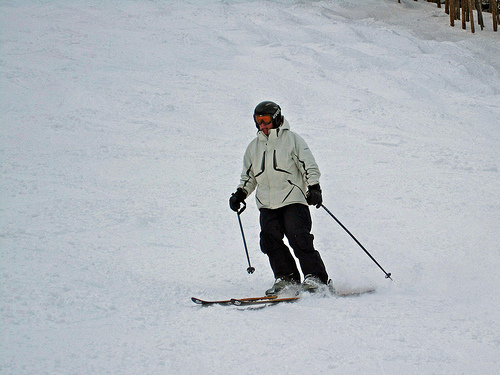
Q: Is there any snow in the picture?
A: Yes, there is snow.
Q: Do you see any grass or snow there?
A: Yes, there is snow.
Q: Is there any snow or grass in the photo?
A: Yes, there is snow.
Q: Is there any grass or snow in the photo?
A: Yes, there is snow.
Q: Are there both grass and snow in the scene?
A: No, there is snow but no grass.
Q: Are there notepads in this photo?
A: No, there are no notepads.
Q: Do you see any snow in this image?
A: Yes, there is snow.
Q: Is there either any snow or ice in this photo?
A: Yes, there is snow.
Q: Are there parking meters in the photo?
A: No, there are no parking meters.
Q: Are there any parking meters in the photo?
A: No, there are no parking meters.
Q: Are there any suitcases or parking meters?
A: No, there are no parking meters or suitcases.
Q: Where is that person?
A: The person is on the snow.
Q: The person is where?
A: The person is in the snow.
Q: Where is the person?
A: The person is on the snow.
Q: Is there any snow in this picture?
A: Yes, there is snow.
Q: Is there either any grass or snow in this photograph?
A: Yes, there is snow.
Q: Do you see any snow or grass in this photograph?
A: Yes, there is snow.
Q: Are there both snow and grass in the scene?
A: No, there is snow but no grass.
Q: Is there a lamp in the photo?
A: No, there are no lamps.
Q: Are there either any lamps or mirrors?
A: No, there are no lamps or mirrors.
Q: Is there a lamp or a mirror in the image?
A: No, there are no lamps or mirrors.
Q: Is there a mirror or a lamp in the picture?
A: No, there are no lamps or mirrors.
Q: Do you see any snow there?
A: Yes, there is snow.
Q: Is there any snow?
A: Yes, there is snow.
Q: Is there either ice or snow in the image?
A: Yes, there is snow.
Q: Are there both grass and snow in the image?
A: No, there is snow but no grass.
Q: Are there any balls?
A: No, there are no balls.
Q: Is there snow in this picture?
A: Yes, there is snow.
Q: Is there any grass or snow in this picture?
A: Yes, there is snow.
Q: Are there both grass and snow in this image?
A: No, there is snow but no grass.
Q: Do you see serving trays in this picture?
A: No, there are no serving trays.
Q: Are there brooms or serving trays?
A: No, there are no serving trays or brooms.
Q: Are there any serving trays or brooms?
A: No, there are no serving trays or brooms.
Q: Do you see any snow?
A: Yes, there is snow.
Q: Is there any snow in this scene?
A: Yes, there is snow.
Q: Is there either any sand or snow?
A: Yes, there is snow.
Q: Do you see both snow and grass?
A: No, there is snow but no grass.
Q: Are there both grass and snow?
A: No, there is snow but no grass.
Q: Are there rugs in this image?
A: No, there are no rugs.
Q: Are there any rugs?
A: No, there are no rugs.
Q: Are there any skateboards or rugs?
A: No, there are no rugs or skateboards.